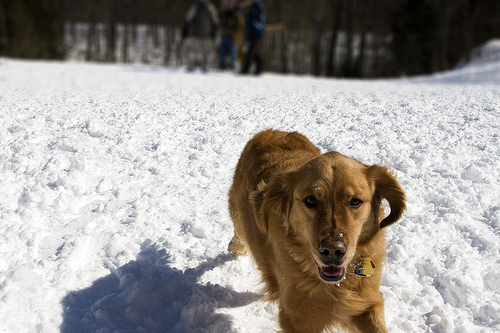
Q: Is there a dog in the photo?
A: Yes, there is a dog.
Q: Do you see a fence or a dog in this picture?
A: Yes, there is a dog.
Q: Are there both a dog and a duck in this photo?
A: No, there is a dog but no ducks.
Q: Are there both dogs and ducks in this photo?
A: No, there is a dog but no ducks.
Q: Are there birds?
A: No, there are no birds.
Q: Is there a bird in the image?
A: No, there are no birds.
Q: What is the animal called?
A: The animal is a dog.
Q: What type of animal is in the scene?
A: The animal is a dog.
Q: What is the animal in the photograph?
A: The animal is a dog.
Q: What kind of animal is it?
A: The animal is a dog.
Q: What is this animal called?
A: This is a dog.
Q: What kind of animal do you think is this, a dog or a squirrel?
A: This is a dog.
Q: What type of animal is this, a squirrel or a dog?
A: This is a dog.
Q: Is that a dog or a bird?
A: That is a dog.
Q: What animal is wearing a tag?
A: The dog is wearing a tag.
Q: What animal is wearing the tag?
A: The dog is wearing a tag.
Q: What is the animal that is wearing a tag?
A: The animal is a dog.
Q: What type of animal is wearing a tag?
A: The animal is a dog.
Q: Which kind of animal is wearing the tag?
A: The animal is a dog.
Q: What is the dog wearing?
A: The dog is wearing a tag.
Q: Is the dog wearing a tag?
A: Yes, the dog is wearing a tag.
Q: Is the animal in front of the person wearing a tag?
A: Yes, the dog is wearing a tag.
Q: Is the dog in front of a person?
A: Yes, the dog is in front of a person.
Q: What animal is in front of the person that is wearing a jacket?
A: The dog is in front of the person.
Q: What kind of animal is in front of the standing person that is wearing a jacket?
A: The animal is a dog.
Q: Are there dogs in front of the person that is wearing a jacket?
A: Yes, there is a dog in front of the person.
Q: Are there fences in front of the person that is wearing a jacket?
A: No, there is a dog in front of the person.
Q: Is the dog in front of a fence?
A: No, the dog is in front of a person.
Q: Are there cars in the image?
A: No, there are no cars.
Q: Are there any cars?
A: No, there are no cars.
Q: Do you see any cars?
A: No, there are no cars.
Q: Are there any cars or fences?
A: No, there are no cars or fences.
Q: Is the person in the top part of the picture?
A: Yes, the person is in the top of the image.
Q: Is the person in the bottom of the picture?
A: No, the person is in the top of the image.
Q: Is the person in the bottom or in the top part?
A: The person is in the top of the image.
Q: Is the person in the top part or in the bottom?
A: The person is in the top of the image.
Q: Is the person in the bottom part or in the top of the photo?
A: The person is in the top of the image.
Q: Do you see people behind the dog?
A: Yes, there is a person behind the dog.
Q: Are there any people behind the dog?
A: Yes, there is a person behind the dog.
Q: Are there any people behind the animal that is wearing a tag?
A: Yes, there is a person behind the dog.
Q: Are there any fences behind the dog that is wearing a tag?
A: No, there is a person behind the dog.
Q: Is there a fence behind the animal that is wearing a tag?
A: No, there is a person behind the dog.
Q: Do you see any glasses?
A: No, there are no glasses.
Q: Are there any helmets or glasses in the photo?
A: No, there are no glasses or helmets.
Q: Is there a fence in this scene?
A: No, there are no fences.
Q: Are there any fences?
A: No, there are no fences.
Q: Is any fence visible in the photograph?
A: No, there are no fences.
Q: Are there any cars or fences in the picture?
A: No, there are no fences or cars.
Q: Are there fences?
A: No, there are no fences.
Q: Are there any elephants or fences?
A: No, there are no fences or elephants.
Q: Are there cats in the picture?
A: No, there are no cats.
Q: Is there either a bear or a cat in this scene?
A: No, there are no cats or bears.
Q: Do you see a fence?
A: No, there are no fences.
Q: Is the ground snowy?
A: Yes, the ground is snowy.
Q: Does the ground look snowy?
A: Yes, the ground is snowy.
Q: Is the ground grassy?
A: No, the ground is snowy.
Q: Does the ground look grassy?
A: No, the ground is snowy.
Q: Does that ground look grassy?
A: No, the ground is snowy.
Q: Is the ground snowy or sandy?
A: The ground is snowy.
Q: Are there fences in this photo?
A: No, there are no fences.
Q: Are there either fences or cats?
A: No, there are no fences or cats.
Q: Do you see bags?
A: No, there are no bags.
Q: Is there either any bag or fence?
A: No, there are no bags or fences.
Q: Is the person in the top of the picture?
A: Yes, the person is in the top of the image.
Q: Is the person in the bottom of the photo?
A: No, the person is in the top of the image.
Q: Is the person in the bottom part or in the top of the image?
A: The person is in the top of the image.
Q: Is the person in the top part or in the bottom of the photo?
A: The person is in the top of the image.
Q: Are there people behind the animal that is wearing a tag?
A: Yes, there is a person behind the dog.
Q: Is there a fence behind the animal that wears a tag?
A: No, there is a person behind the dog.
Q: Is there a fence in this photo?
A: No, there are no fences.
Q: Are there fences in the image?
A: No, there are no fences.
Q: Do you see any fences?
A: No, there are no fences.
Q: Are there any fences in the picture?
A: No, there are no fences.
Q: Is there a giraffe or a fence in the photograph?
A: No, there are no fences or giraffes.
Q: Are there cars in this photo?
A: No, there are no cars.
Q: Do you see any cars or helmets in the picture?
A: No, there are no cars or helmets.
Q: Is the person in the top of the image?
A: Yes, the person is in the top of the image.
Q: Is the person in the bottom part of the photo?
A: No, the person is in the top of the image.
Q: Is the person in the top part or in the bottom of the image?
A: The person is in the top of the image.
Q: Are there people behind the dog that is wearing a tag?
A: Yes, there is a person behind the dog.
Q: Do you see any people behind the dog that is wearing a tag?
A: Yes, there is a person behind the dog.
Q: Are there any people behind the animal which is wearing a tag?
A: Yes, there is a person behind the dog.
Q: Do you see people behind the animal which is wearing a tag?
A: Yes, there is a person behind the dog.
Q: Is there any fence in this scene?
A: No, there are no fences.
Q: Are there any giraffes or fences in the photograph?
A: No, there are no fences or giraffes.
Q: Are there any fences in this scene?
A: No, there are no fences.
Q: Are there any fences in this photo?
A: No, there are no fences.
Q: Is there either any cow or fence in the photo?
A: No, there are no fences or cows.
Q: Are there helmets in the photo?
A: No, there are no helmets.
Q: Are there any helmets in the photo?
A: No, there are no helmets.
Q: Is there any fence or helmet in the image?
A: No, there are no helmets or fences.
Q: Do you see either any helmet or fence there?
A: No, there are no helmets or fences.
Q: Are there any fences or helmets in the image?
A: No, there are no helmets or fences.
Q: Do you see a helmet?
A: No, there are no helmets.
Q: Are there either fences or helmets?
A: No, there are no helmets or fences.